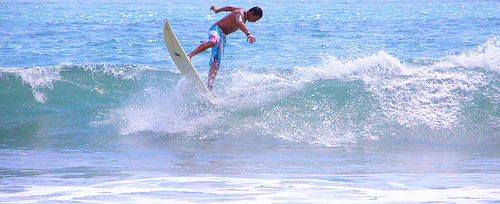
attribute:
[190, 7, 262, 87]
man — surfing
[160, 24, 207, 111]
surfboard — white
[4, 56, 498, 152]
waves — medium, splashing, rolling, foamy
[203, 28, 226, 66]
shorts — blue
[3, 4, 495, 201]
ocean — blue, beautiful, water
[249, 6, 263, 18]
hair — black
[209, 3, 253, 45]
arms — extended